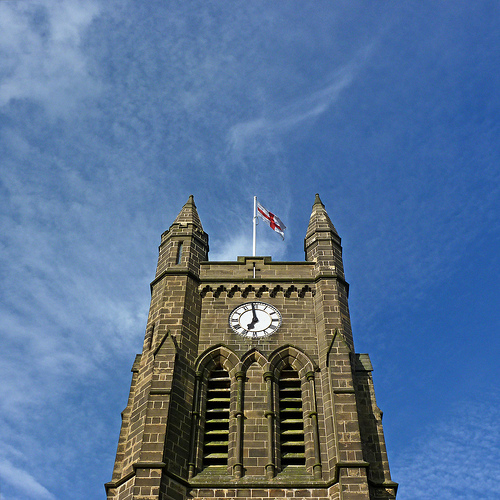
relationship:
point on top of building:
[305, 192, 334, 228] [105, 194, 401, 499]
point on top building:
[172, 195, 203, 228] [105, 194, 401, 499]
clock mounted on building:
[228, 301, 280, 339] [105, 194, 401, 499]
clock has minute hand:
[228, 301, 280, 339] [250, 303, 259, 323]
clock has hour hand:
[228, 301, 280, 339] [246, 319, 258, 333]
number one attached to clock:
[263, 305, 268, 313] [228, 301, 280, 339]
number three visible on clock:
[271, 318, 280, 323] [228, 301, 280, 339]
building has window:
[105, 194, 401, 499] [279, 368, 305, 469]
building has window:
[105, 194, 401, 499] [202, 371, 231, 467]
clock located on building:
[228, 301, 280, 339] [105, 194, 401, 499]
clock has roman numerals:
[228, 301, 280, 339] [232, 305, 279, 337]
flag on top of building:
[254, 197, 286, 242] [105, 194, 401, 499]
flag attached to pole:
[254, 197, 286, 242] [251, 194, 258, 257]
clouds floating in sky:
[1, 2, 400, 499] [0, 0, 497, 499]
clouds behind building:
[1, 2, 400, 499] [105, 194, 401, 499]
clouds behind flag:
[1, 2, 400, 499] [254, 197, 286, 242]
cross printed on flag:
[258, 208, 283, 235] [254, 197, 286, 242]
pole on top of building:
[251, 194, 258, 257] [105, 194, 401, 499]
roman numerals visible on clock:
[232, 305, 279, 337] [228, 301, 280, 339]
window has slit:
[279, 368, 305, 469] [279, 376, 300, 384]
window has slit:
[279, 368, 305, 469] [281, 395, 305, 404]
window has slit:
[279, 368, 305, 469] [282, 405, 302, 414]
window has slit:
[279, 368, 305, 469] [279, 416, 302, 426]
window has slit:
[279, 368, 305, 469] [285, 439, 305, 447]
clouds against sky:
[1, 2, 400, 499] [0, 0, 497, 499]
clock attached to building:
[228, 301, 280, 339] [105, 194, 401, 499]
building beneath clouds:
[105, 194, 401, 499] [1, 2, 400, 499]